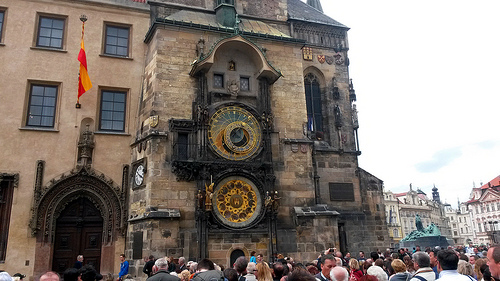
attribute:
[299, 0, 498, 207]
cloudy sky — white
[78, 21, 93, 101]
flag — red, yellow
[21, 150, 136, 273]
doorway — arched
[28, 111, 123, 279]
doorway —  arched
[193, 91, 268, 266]
clock — ornate, outdoor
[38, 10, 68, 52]
window — multipaned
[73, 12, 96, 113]
flag — orange, red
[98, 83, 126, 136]
window — multipaned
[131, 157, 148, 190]
clock — outdoors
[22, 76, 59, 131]
window — multipaned